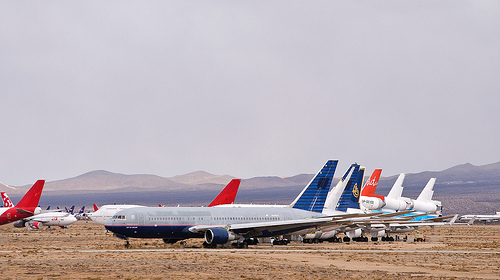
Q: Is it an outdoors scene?
A: Yes, it is outdoors.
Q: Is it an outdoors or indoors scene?
A: It is outdoors.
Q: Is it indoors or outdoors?
A: It is outdoors.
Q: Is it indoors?
A: No, it is outdoors.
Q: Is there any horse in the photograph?
A: No, there are no horses.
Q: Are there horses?
A: No, there are no horses.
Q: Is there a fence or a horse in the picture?
A: No, there are no horses or fences.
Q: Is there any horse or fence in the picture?
A: No, there are no horses or fences.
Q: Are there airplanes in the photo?
A: Yes, there are airplanes.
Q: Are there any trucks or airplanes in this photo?
A: Yes, there are airplanes.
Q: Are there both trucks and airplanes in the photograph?
A: No, there are airplanes but no trucks.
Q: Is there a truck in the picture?
A: No, there are no trucks.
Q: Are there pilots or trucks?
A: No, there are no trucks or pilots.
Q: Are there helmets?
A: No, there are no helmets.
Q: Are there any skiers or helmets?
A: No, there are no helmets or skiers.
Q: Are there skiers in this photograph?
A: No, there are no skiers.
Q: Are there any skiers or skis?
A: No, there are no skiers or skis.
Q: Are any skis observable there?
A: No, there are no skis.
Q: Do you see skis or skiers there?
A: No, there are no skis or skiers.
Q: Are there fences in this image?
A: No, there are no fences.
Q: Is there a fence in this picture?
A: No, there are no fences.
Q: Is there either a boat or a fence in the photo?
A: No, there are no fences or boats.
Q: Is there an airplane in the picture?
A: Yes, there is an airplane.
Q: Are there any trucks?
A: No, there are no trucks.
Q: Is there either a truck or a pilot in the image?
A: No, there are no trucks or pilots.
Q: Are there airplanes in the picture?
A: Yes, there is an airplane.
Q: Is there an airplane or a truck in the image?
A: Yes, there is an airplane.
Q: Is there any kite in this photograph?
A: No, there are no kites.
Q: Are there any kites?
A: No, there are no kites.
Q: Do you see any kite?
A: No, there are no kites.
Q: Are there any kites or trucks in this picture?
A: No, there are no kites or trucks.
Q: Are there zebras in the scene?
A: No, there are no zebras.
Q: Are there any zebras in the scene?
A: No, there are no zebras.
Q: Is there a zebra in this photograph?
A: No, there are no zebras.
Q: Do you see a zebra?
A: No, there are no zebras.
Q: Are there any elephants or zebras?
A: No, there are no zebras or elephants.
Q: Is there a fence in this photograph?
A: No, there are no fences.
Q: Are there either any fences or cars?
A: No, there are no fences or cars.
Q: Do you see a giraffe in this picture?
A: No, there are no giraffes.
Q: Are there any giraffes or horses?
A: No, there are no giraffes or horses.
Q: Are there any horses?
A: No, there are no horses.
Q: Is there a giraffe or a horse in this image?
A: No, there are no horses or giraffes.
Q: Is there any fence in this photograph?
A: No, there are no fences.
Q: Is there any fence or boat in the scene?
A: No, there are no fences or boats.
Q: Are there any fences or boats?
A: No, there are no fences or boats.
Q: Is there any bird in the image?
A: No, there are no birds.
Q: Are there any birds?
A: No, there are no birds.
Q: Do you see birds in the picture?
A: No, there are no birds.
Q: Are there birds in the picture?
A: No, there are no birds.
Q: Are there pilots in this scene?
A: No, there are no pilots.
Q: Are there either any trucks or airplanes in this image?
A: Yes, there is an airplane.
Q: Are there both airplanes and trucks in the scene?
A: No, there is an airplane but no trucks.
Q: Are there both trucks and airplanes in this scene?
A: No, there is an airplane but no trucks.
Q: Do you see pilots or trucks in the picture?
A: No, there are no pilots or trucks.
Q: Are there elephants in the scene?
A: No, there are no elephants.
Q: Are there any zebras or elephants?
A: No, there are no elephants or zebras.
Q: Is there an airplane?
A: Yes, there is an airplane.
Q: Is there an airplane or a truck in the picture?
A: Yes, there is an airplane.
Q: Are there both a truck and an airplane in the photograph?
A: No, there is an airplane but no trucks.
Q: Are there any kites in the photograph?
A: No, there are no kites.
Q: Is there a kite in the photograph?
A: No, there are no kites.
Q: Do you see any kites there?
A: No, there are no kites.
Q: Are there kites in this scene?
A: No, there are no kites.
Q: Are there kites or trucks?
A: No, there are no kites or trucks.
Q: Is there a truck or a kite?
A: No, there are no kites or trucks.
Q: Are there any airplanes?
A: Yes, there is an airplane.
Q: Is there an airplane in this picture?
A: Yes, there is an airplane.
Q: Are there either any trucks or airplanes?
A: Yes, there is an airplane.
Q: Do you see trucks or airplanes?
A: Yes, there is an airplane.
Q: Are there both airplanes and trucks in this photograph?
A: No, there is an airplane but no trucks.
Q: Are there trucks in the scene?
A: No, there are no trucks.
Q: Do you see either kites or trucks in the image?
A: No, there are no trucks or kites.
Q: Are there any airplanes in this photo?
A: Yes, there is an airplane.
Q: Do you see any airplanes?
A: Yes, there is an airplane.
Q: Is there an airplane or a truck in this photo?
A: Yes, there is an airplane.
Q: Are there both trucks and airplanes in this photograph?
A: No, there is an airplane but no trucks.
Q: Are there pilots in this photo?
A: No, there are no pilots.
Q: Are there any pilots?
A: No, there are no pilots.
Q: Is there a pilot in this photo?
A: No, there are no pilots.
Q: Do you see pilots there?
A: No, there are no pilots.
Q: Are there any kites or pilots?
A: No, there are no pilots or kites.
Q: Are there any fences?
A: No, there are no fences.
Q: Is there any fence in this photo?
A: No, there are no fences.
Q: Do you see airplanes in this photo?
A: Yes, there is an airplane.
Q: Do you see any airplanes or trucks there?
A: Yes, there is an airplane.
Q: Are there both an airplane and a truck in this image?
A: No, there is an airplane but no trucks.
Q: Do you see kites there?
A: No, there are no kites.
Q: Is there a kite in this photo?
A: No, there are no kites.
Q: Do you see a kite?
A: No, there are no kites.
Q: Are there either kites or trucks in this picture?
A: No, there are no kites or trucks.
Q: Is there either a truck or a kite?
A: No, there are no kites or trucks.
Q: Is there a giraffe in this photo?
A: No, there are no giraffes.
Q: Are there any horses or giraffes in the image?
A: No, there are no giraffes or horses.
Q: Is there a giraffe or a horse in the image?
A: No, there are no giraffes or horses.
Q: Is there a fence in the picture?
A: No, there are no fences.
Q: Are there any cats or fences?
A: No, there are no fences or cats.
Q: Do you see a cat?
A: No, there are no cats.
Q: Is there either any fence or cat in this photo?
A: No, there are no cats or fences.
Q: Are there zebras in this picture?
A: No, there are no zebras.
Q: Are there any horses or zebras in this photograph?
A: No, there are no zebras or horses.